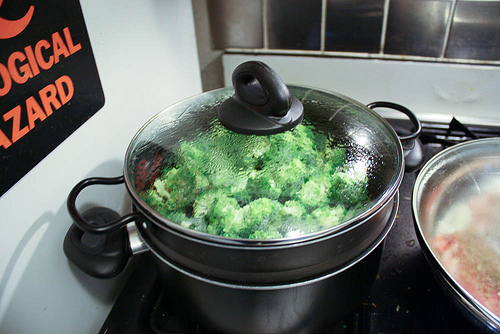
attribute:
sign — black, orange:
[1, 1, 105, 204]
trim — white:
[217, 33, 497, 80]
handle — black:
[45, 207, 137, 289]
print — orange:
[3, 5, 85, 158]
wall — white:
[106, 19, 173, 76]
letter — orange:
[0, 0, 92, 137]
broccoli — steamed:
[137, 117, 375, 242]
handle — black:
[223, 58, 304, 125]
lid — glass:
[124, 67, 401, 234]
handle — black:
[226, 42, 306, 139]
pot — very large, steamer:
[34, 52, 461, 331]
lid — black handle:
[132, 59, 399, 224]